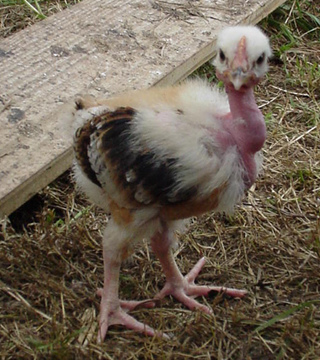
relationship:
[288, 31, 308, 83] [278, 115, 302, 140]
dry grass on ground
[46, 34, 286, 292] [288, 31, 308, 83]
hen on dry grass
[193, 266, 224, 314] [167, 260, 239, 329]
toes on foot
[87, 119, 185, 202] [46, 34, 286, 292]
wing on hen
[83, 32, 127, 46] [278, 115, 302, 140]
board on ground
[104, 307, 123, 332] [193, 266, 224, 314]
webbing between toes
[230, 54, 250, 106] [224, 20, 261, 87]
beak on face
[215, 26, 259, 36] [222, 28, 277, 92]
fluff on head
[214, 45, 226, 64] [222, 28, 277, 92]
eye on head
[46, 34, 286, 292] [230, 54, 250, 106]
hen has beak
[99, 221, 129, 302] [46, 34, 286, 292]
leg of hen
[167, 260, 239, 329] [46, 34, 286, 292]
foot of hen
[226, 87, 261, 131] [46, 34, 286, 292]
neck of hen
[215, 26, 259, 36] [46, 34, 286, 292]
fluff on hen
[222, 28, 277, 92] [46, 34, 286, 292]
head of hen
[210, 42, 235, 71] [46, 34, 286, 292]
eye of hen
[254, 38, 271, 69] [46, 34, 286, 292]
eye of hen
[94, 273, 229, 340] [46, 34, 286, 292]
feet on hen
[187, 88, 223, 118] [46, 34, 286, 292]
feathers on hen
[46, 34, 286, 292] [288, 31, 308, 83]
hen in dry grass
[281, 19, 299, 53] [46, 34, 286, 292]
grass under hen